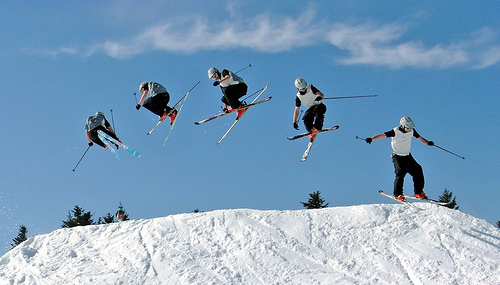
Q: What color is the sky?
A: Blue.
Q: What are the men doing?
A: Ski stunts.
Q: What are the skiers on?
A: Hill.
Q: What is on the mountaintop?
A: Skiers.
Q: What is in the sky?
A: Clouds.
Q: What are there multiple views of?
A: A skier jumping.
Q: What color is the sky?
A: Blue.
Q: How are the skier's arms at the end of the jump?
A: Arms are out.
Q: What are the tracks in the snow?
A: Ski tracks.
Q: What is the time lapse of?
A: A skier jumping.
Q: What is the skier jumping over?
A: A snowy hill.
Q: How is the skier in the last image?
A: Landing.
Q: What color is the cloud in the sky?
A: White.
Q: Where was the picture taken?
A: On a ski slope.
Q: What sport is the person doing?
A: Skiing.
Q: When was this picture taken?
A: Daytime.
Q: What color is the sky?
A: Blue.